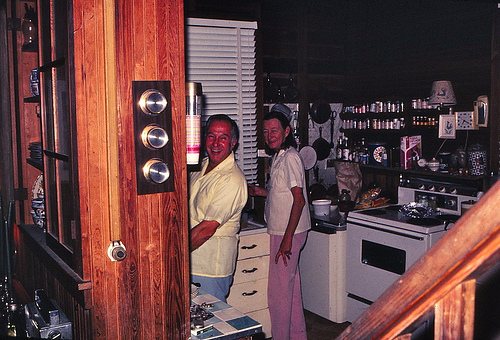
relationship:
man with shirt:
[188, 115, 249, 304] [191, 151, 248, 280]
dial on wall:
[141, 160, 172, 186] [74, 1, 190, 338]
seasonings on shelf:
[341, 99, 407, 136] [338, 111, 409, 119]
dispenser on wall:
[186, 80, 205, 170] [74, 1, 190, 338]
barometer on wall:
[131, 81, 176, 196] [74, 1, 190, 338]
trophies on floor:
[0, 277, 20, 338] [1, 275, 53, 339]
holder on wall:
[184, 79, 203, 118] [74, 1, 190, 338]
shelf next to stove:
[338, 111, 409, 119] [346, 205, 458, 323]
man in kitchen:
[188, 115, 249, 304] [184, 1, 498, 338]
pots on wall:
[264, 76, 302, 104] [188, 3, 370, 205]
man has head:
[188, 115, 249, 304] [203, 113, 240, 161]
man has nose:
[188, 115, 249, 304] [211, 138, 221, 148]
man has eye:
[188, 115, 249, 304] [208, 133, 213, 139]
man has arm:
[188, 115, 249, 304] [190, 173, 249, 252]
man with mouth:
[188, 115, 249, 304] [208, 146, 224, 156]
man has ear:
[188, 115, 249, 304] [232, 138, 239, 147]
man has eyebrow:
[188, 115, 249, 304] [219, 132, 229, 138]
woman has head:
[249, 113, 313, 339] [262, 112, 292, 151]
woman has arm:
[249, 113, 313, 339] [275, 150, 308, 267]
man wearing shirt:
[188, 115, 249, 304] [191, 151, 248, 280]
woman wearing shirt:
[249, 113, 313, 339] [265, 147, 316, 235]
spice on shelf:
[375, 101, 382, 112] [338, 111, 409, 119]